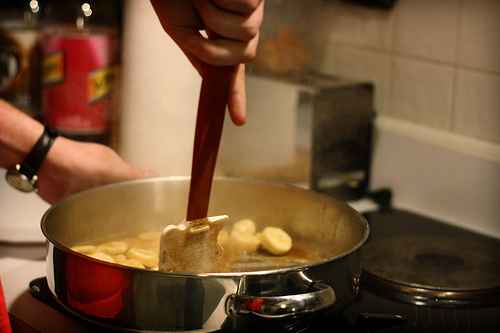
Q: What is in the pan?
A: Banana slices.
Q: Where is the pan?
A: On the stove.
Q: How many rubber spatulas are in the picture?
A: 1.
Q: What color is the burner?
A: Black.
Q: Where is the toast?
A: In the toaster.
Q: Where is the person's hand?
A: On the spatula.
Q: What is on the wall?
A: Tile.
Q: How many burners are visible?
A: 1.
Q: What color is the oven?
A: Black.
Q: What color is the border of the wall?
A: White.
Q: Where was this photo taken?
A: In a kitchen.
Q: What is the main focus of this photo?
A: Food being cooked.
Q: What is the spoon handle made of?
A: Wood.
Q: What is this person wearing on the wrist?
A: A black strapped watch.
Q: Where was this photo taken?
A: Inside a person's home.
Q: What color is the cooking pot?
A: Silver.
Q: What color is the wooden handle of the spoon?
A: Brown.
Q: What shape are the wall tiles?
A: Square.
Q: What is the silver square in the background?
A: A toaster.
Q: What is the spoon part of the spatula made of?
A: Plastic.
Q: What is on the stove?
A: A pan.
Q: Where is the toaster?
A: By the wall.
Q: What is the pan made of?
A: Steel.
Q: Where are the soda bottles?
A: By the paper towels.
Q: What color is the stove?
A: Black.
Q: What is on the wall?
A: Tiles.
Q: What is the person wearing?
A: A watch.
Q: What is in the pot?
A: Potatoes.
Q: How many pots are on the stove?
A: One.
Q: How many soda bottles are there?
A: Two.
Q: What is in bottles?
A: Non alcoholic beverages.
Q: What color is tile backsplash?
A: White.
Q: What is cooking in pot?
A: Bananas.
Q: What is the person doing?
A: Cooking.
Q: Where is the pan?
A: On the burner.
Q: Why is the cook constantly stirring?
A: To avoid burning.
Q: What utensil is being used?
A: A spatula.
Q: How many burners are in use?
A: 1.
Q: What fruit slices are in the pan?
A: Bananas.